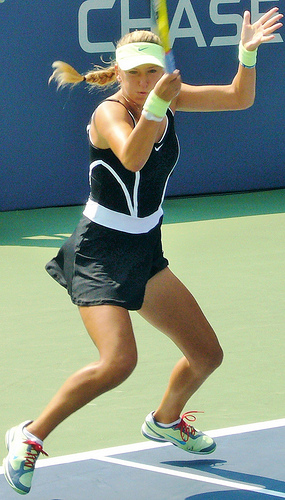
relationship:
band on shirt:
[82, 196, 165, 237] [84, 98, 182, 233]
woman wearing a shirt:
[4, 3, 283, 495] [84, 98, 182, 233]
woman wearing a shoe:
[4, 3, 283, 495] [3, 419, 40, 494]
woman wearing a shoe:
[4, 3, 283, 495] [141, 409, 218, 458]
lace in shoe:
[23, 439, 49, 470] [3, 419, 40, 494]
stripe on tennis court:
[0, 415, 285, 475] [0, 188, 282, 496]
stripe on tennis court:
[95, 455, 281, 498] [0, 188, 282, 496]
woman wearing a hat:
[4, 3, 283, 495] [112, 40, 167, 70]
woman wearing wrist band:
[4, 3, 283, 495] [235, 42, 256, 66]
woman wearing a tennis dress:
[4, 3, 283, 495] [45, 93, 182, 311]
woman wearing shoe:
[4, 3, 283, 495] [3, 419, 40, 494]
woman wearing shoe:
[4, 3, 283, 495] [141, 409, 218, 458]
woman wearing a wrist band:
[4, 3, 283, 495] [235, 42, 256, 66]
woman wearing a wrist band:
[4, 3, 283, 495] [142, 90, 173, 118]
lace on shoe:
[23, 439, 49, 470] [3, 419, 40, 494]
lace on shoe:
[177, 408, 200, 445] [141, 409, 218, 458]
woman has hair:
[4, 3, 283, 495] [47, 27, 163, 91]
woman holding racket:
[4, 3, 283, 495] [149, 1, 175, 73]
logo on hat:
[134, 44, 149, 53] [112, 40, 167, 70]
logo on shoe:
[162, 434, 186, 448] [141, 409, 218, 458]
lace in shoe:
[177, 408, 200, 445] [141, 409, 218, 458]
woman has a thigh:
[4, 3, 283, 495] [134, 267, 194, 336]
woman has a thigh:
[4, 3, 283, 495] [76, 302, 136, 338]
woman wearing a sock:
[4, 3, 283, 495] [155, 418, 186, 426]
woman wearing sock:
[4, 3, 283, 495] [23, 430, 46, 446]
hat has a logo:
[112, 40, 167, 70] [134, 44, 149, 53]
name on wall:
[76, 0, 284, 53] [2, 0, 283, 213]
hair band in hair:
[82, 74, 89, 84] [47, 27, 163, 91]